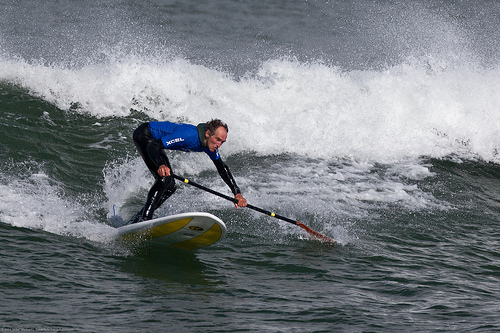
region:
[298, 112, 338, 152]
part of a splash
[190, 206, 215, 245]
edge of a board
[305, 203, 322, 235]
part of a water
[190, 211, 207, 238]
part pf a bard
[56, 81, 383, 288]
this person is surfing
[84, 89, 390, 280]
this person is paddle boarding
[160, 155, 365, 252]
this is a paddle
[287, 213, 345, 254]
the paddle is orange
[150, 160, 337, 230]
the handle is long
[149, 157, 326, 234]
the handle is black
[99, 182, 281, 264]
the board has yellow stripes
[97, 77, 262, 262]
he is wearing a black and blue wetsuit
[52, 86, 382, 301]
he is surfing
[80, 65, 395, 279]
the is surfing on the surface of the water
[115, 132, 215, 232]
man is on board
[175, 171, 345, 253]
black and yellow pole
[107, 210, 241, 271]
white and yellow board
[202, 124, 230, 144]
man has brown hair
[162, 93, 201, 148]
blue and white shirt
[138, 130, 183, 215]
man has black pants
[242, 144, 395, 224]
white water behind man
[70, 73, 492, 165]
white wave is crashing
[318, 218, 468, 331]
water is dark grey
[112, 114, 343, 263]
man has paddle in water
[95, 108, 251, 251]
Man on a surfboard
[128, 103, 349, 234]
Man holding a paddle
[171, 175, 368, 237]
Paddle touching the water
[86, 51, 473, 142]
Splash of a wave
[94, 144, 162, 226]
White spray from surfboard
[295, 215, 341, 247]
Red end of paddle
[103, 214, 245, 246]
White and yellow surfboard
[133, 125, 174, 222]
Black surfing pants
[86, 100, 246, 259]
Man surfings with a paddle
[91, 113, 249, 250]
Man riding a wave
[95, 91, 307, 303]
a man on a paddle board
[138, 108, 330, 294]
a man holding a paddle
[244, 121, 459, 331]
a body of water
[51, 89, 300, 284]
a man wearing a wetsuit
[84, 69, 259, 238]
a man ewarin g ab lue and black wetusit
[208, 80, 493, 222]
a wave on the water